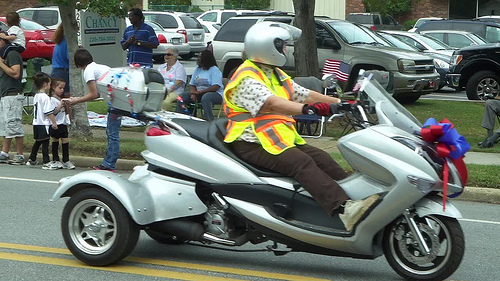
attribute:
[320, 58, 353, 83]
flag — behind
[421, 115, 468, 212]
ribbon — blue, red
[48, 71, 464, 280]
vehicle — silver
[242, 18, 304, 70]
helmet — silver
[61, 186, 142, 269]
tire — rubber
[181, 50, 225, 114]
spectator — sitting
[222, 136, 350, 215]
pants — brown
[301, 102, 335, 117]
glove — red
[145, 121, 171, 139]
taillight — red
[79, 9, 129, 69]
sign — white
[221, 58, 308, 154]
vest — yellow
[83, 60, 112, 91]
shirt — white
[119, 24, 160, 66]
polo — blue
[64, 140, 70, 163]
socks — black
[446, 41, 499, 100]
truck — black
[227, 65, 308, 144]
blouse — spotted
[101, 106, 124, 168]
jeans — blue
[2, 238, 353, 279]
line — yellow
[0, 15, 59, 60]
car — red